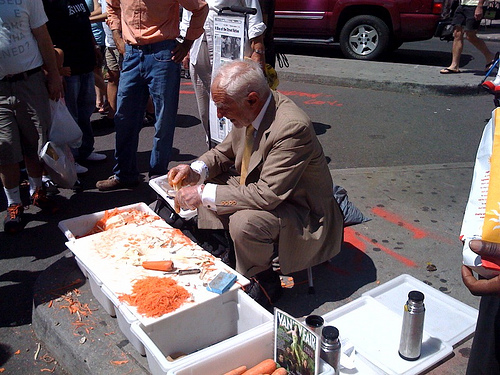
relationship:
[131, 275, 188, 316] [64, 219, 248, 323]
carrot on cutting board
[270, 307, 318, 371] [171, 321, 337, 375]
magazine inside box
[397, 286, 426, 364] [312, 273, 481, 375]
thermo on top of board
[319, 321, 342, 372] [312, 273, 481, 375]
thermo on top of board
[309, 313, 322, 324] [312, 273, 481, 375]
thermo on top of board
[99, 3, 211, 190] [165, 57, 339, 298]
spectator watching man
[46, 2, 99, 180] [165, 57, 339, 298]
spectator watching man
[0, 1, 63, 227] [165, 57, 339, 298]
spectator watching man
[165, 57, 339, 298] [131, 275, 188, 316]
man cutting carrot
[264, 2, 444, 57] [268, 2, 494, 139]
vehicle in background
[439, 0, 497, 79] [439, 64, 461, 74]
woman wearing flip flops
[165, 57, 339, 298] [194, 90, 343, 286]
man wearing suit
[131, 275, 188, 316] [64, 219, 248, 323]
carrot on top of cutting board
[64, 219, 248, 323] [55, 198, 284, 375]
cutting board on top of boxes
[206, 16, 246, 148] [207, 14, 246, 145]
newspaper on display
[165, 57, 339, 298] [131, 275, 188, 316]
man peeling carrot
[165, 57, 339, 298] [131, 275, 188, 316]
man demonstrating with carrot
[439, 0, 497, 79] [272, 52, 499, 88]
woman on sidewalk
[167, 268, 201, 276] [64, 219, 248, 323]
carrot peeler on top of cutting board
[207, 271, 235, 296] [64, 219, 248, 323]
sponge on top of cutting board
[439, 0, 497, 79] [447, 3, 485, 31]
woman wearing shorts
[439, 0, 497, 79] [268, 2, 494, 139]
woman walking in background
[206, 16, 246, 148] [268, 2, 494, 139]
newspaper in background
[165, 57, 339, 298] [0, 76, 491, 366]
man in road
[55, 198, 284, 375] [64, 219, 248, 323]
boxes are under cutting board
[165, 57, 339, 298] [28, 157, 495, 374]
man in sidewalk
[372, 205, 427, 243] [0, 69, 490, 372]
paint on ground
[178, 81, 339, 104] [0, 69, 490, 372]
paint on ground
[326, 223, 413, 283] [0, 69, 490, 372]
paint on ground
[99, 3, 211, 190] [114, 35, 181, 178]
spectator wearing jeans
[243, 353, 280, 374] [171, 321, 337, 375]
carrot inside container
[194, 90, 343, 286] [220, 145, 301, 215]
suit has wrinkles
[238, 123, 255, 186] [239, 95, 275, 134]
tie around neck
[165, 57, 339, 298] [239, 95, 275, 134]
man has neck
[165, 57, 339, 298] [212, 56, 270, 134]
man has head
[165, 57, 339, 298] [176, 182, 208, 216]
man has hand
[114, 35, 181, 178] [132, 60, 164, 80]
jeans has section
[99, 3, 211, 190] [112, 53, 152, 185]
spectator has leg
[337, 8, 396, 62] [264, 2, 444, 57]
wheel from vehicle